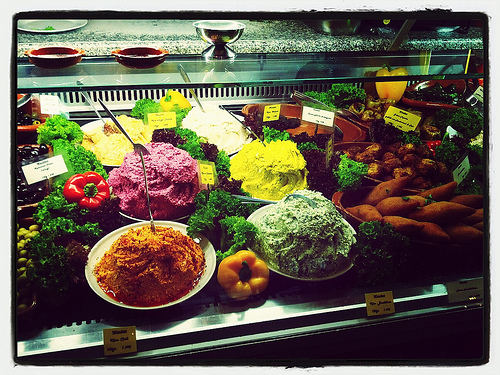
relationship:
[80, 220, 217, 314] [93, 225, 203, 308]
bowl containing food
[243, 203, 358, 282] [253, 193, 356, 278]
bowl containing food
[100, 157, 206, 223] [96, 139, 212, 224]
bowl containing food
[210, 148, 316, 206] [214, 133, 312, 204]
bowl containing food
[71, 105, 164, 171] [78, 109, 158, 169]
bowl containing food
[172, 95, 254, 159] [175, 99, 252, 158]
bowl containing food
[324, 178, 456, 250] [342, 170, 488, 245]
bowl containing food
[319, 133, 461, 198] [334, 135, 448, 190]
bowl containing food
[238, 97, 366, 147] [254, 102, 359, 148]
bowl containing food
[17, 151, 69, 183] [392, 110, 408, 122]
sign with lettering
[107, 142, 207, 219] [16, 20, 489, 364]
food on salad bar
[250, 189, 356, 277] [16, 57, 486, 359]
food on salad bar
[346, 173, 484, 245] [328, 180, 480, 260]
sweet potatoes in brown bowl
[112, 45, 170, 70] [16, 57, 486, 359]
bowl on salad bar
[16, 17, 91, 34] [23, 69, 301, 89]
plate sitting shelf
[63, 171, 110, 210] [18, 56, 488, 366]
bell pepper in case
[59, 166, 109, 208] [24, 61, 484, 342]
bell pepper in case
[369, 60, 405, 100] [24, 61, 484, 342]
bell pepper in case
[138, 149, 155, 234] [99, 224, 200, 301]
utensil in food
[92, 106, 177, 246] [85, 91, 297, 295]
utensil in food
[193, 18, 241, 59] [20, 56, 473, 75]
bowl on top of case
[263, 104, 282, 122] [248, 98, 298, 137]
yellow sign with writing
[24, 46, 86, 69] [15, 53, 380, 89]
bowl laying on shelf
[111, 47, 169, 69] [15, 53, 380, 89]
bowl laying on shelf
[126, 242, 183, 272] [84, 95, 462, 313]
food on on display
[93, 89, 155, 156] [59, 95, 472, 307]
spoons in food